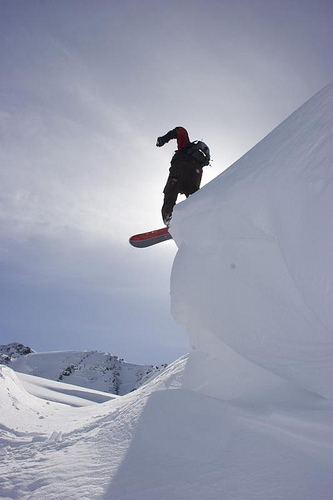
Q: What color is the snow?
A: White.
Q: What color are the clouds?
A: White.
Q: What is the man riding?
A: Snowboard.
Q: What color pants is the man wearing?
A: Black.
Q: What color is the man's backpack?
A: Black.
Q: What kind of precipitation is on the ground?
A: Snow.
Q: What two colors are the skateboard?
A: Red and gray.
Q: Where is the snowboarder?
A: Ledge of mountain.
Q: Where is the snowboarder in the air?
A: Mid air.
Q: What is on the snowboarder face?
A: Goggles.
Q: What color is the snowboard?
A: Red.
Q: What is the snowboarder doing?
A: Trick in air.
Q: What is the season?
A: Winter.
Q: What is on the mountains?
A: Snow.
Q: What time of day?
A: Daytime.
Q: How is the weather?
A: Cold and sunny.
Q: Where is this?
A: On a ski slope.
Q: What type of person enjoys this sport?
A: Adrenaline junkies.